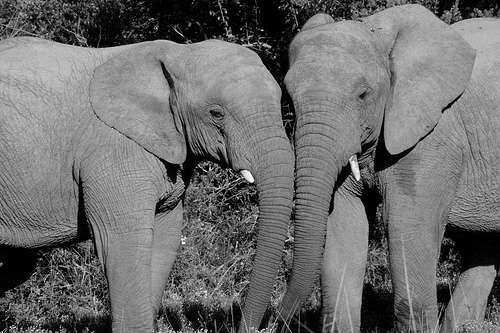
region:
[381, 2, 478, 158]
the ear of an elephant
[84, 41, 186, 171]
the ear of an elephant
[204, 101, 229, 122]
the eye of an elephant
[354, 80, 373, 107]
the eye of an elephant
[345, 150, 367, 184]
the tusk of an elephant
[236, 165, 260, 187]
the tusk of an elephant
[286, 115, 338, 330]
the trunk of a elephant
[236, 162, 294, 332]
the tusk of an elephant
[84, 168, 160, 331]
the front leg of an elephant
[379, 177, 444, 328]
the front leg of an elephant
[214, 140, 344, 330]
the elephants are touching noses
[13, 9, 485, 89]
trees can be seen in the background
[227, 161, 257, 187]
the smaller elephants tusk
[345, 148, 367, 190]
the larger elephants tusk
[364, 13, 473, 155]
the larger elephants ear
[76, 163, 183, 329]
the smaller elephants front legs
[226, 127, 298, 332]
the smaller elehants trunk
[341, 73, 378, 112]
the larger elephants eye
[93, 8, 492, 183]
two elephants heads are pictured here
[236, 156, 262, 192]
white tusk of elephant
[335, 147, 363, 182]
white tusk of elephant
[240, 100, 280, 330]
long elephant trunk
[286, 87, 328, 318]
long elephant trunk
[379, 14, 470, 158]
elephant's big floppy ear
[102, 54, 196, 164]
elephant's big floppy ear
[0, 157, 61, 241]
wrinkled hide of animal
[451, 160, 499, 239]
hide of animal is wrinkled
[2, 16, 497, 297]
two gray adult elephants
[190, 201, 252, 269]
bushes in back ground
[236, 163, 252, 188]
The elephant's tusk is white.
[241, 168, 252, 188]
The elephants tusk is short.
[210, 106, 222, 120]
The elephants eye is black.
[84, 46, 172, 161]
The elephants ear is gray.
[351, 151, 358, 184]
The elephants tusk is white.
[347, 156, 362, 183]
The elephants tusk is short.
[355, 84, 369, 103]
The elephants eye is black.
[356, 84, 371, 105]
The elephants eye is small.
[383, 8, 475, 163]
The elephants ear is gray.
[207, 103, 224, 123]
The elephants eye is small.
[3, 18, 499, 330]
two happy elephants standing together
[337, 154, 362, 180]
the tusk of the elephant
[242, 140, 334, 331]
the two trunks right next to each other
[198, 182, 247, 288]
a bush with some leaves on it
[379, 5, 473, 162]
a big elephant ear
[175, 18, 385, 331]
two elephants looking like they are trying to hug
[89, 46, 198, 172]
a little elephant ear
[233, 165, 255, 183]
a little tusk sticking out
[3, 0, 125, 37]
a tree behind the elephant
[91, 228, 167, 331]
the front legs of the elephant